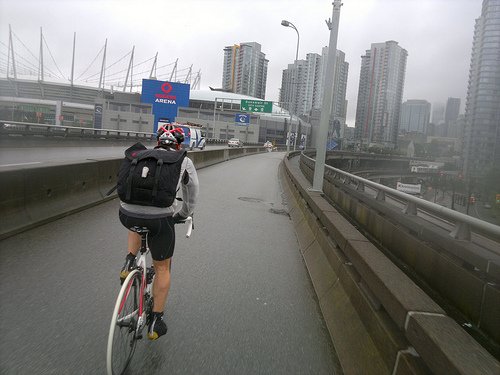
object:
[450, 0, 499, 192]
skyscraper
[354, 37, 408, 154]
skyscraper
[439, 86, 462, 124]
skyscraper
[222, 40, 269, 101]
skyscraper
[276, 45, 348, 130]
skyscraper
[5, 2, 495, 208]
downtown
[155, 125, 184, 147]
bicycle helmet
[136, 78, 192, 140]
blue billboard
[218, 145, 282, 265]
highway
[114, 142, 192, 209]
backpack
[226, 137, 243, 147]
silver car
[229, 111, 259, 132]
blue sign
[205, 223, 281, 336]
ground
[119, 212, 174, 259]
shorts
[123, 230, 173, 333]
legs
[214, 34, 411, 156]
buildings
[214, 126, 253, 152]
car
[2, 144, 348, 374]
path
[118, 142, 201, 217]
shirt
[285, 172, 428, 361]
concrete barrier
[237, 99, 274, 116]
road sign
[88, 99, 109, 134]
sign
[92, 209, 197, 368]
bicycle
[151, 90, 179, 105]
lettering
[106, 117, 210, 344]
bicyclist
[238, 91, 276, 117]
sign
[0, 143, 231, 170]
street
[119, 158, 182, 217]
man's back